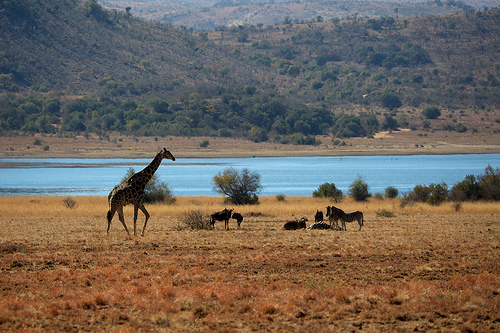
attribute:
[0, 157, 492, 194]
water — blue, blue colored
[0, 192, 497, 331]
ground — brown, grass, red, yellow, dirt, brown colored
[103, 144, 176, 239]
giraffe — wild, walking, facing right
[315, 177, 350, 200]
bush — wild, green, tumble weed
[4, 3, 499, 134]
hill — grassy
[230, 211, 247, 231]
animal — baby, standing still, in herd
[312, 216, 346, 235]
animal — dead, laying down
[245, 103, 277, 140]
tree — treen